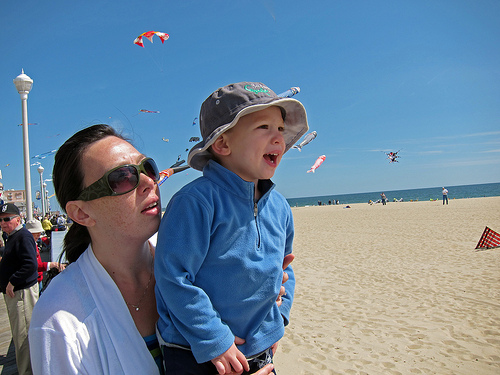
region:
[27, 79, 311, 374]
Women and child at the beach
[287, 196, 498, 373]
Wide stretch of sandy beach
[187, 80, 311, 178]
Floppy blue hat on boy's head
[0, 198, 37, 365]
Man standing on boardwalk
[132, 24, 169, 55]
Red and white kite in the sky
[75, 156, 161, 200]
Sunglasses over woman's eyes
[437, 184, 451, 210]
Person standing near water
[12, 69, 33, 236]
White lamp post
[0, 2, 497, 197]
Cloudless blue sky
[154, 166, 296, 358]
Boy's blue fleece sweater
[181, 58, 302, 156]
young person wearing hat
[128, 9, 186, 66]
red kite in sky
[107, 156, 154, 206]
sun glasses worn by woman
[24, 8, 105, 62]
white clouds against blue sky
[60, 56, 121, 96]
white clouds against blue sky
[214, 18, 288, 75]
white clouds against blue sky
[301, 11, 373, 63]
white clouds against blue sky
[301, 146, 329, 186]
kite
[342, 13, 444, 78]
white clouds against blue sky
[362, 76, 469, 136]
white clouds against blue sky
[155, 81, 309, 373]
a young boy wearing a hat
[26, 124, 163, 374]
a woman with sun glasses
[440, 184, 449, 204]
a man on the beach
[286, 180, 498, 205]
blue ocean water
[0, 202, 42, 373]
a man wearing sun glasses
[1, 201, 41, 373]
a man wearing a har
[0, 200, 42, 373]
a man in a blue sweater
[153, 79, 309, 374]
a child in a blue pullover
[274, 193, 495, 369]
sand on a beach with footprints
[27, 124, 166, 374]
a woman with dark hair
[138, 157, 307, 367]
THE BOY IS WEARING A LONG SLEEVED SHIRT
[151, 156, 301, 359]
THE BOY'S SHIRT IS BLUE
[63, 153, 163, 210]
THE WOMAN IS WEARING SUNGLASSES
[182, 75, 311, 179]
THE KID IS WEARING A HAT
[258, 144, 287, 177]
THE KID HAS HIS MOUTH OPENED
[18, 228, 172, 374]
THE WOMAN IS WEARING A SWEATER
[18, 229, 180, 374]
THE WOMAN'S SWEATER IS WHITE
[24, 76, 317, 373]
THE WOMAN AND THE KID ARE ON THE BEACH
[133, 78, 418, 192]
THE KITES ARE IN THE SKY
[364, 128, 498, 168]
THE CLOUDS ARE LONG, FAINT AND WISPY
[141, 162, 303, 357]
THE BOY IS WEARING A BLUE SHIRT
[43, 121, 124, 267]
THE WOMAN HAS BROWN HAIR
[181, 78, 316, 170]
THE MAN IS WEARING A HAT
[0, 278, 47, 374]
THE MAN IS WEARING TAN PANTS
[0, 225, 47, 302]
THE MAN IS WEARING A BLACK SWEATER